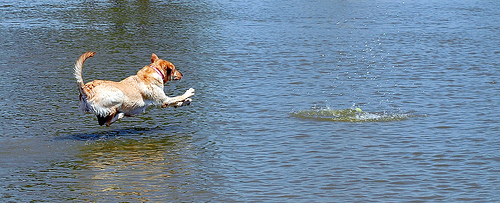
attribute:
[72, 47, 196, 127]
dog — wet, light brown, large, tan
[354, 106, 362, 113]
ball — green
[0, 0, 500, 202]
water — blue, not smooth, calm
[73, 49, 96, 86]
tail — curled, standing up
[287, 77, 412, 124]
splash — wide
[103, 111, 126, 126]
leg — bent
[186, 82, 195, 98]
paw — stretched  out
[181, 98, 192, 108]
paw — stretched  out